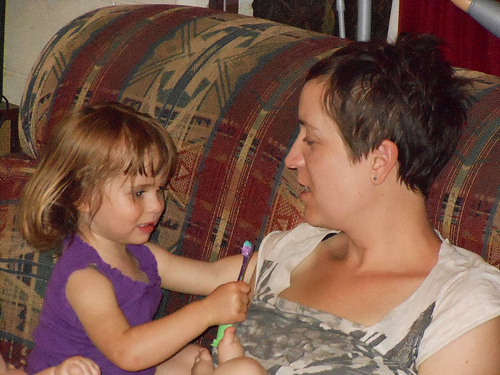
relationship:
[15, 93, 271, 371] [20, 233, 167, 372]
child wearing shirt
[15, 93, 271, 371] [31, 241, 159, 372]
child wearing purple shirt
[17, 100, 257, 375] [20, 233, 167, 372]
child wearing shirt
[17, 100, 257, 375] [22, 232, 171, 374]
child wearing purple shirt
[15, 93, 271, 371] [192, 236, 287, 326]
child holding toothbrush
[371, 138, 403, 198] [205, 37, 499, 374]
ear of woman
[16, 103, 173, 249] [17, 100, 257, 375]
head of child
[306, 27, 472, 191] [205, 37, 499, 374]
hair of woman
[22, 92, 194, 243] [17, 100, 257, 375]
hair of child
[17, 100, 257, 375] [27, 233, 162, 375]
child wearing a purple shirt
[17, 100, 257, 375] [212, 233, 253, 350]
child holding tooth brush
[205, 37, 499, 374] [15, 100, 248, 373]
woman that looking at child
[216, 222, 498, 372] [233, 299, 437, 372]
shirt with some pictures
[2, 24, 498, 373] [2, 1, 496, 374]
people sitting on a couch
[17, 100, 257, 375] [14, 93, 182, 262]
child with hair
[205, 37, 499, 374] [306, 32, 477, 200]
woman with hair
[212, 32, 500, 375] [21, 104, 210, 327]
woman sitting on couch with child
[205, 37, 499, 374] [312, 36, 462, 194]
woman with hair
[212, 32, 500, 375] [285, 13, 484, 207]
woman with hair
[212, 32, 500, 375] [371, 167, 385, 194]
woman with earrings